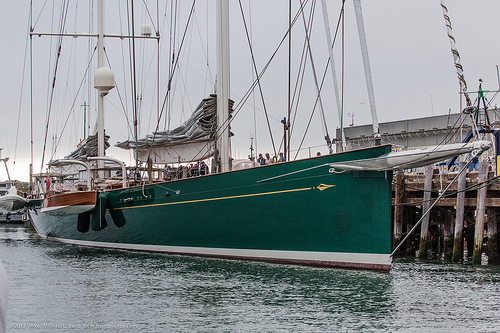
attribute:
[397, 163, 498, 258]
dock — wooden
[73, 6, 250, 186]
mast — white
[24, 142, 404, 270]
sailboat — green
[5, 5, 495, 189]
sky — gray, cloudy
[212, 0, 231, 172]
pole — tall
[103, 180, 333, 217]
arrow — yellow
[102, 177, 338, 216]
arrow — gold, yellow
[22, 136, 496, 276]
boat — docked, green, white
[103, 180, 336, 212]
arrow — yellow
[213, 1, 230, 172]
mast — white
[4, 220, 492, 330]
water — calm, lightly rippling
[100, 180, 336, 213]
stripe — thin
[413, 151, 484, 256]
columns — wooden, tall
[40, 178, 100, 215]
boat — smaller, brown, white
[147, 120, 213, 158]
sail — white, folded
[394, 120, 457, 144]
building — grey, large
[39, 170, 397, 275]
boat — large, green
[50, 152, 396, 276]
boat — green, large